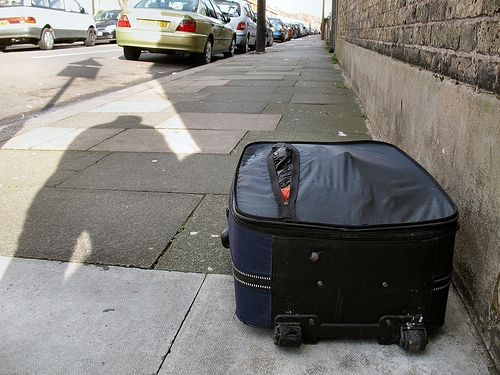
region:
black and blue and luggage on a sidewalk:
[218, 137, 462, 355]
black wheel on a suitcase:
[396, 326, 429, 353]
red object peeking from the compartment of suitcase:
[280, 188, 292, 198]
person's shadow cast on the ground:
[13, 113, 180, 263]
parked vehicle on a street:
[113, 0, 241, 62]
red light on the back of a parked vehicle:
[176, 17, 198, 33]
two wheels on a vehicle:
[37, 23, 97, 48]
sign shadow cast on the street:
[41, 54, 110, 116]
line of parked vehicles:
[113, 0, 312, 60]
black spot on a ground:
[103, 306, 115, 313]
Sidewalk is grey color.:
[31, 141, 174, 306]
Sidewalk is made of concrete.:
[40, 128, 156, 287]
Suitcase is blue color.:
[223, 105, 427, 339]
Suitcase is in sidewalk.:
[229, 120, 453, 342]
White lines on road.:
[13, 43, 87, 88]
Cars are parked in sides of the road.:
[5, 7, 310, 69]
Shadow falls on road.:
[31, 46, 337, 314]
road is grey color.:
[6, 63, 51, 104]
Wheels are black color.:
[264, 313, 436, 363]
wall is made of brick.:
[382, 13, 499, 54]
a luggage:
[297, 55, 445, 373]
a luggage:
[287, 141, 342, 359]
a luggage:
[334, 237, 369, 359]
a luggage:
[282, 158, 339, 373]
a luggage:
[320, 238, 341, 372]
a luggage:
[341, 170, 365, 328]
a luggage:
[304, 114, 329, 369]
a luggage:
[302, 165, 396, 346]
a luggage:
[312, 200, 386, 357]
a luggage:
[318, 238, 348, 365]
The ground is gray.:
[66, 155, 193, 297]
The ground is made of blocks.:
[58, 150, 158, 287]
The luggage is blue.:
[224, 110, 481, 358]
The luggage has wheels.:
[248, 272, 440, 362]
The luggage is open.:
[206, 115, 475, 368]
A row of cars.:
[104, 1, 312, 71]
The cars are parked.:
[106, 0, 323, 81]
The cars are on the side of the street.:
[103, 0, 313, 65]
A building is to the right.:
[332, 0, 496, 373]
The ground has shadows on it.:
[34, 51, 226, 225]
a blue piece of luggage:
[227, 134, 454, 354]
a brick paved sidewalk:
[0, 22, 460, 372]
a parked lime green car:
[116, 0, 234, 65]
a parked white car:
[207, 1, 256, 48]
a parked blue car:
[267, 14, 283, 41]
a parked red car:
[286, 22, 293, 37]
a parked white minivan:
[0, 0, 100, 47]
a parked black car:
[89, 9, 119, 41]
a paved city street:
[1, 13, 185, 110]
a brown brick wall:
[334, 0, 498, 94]